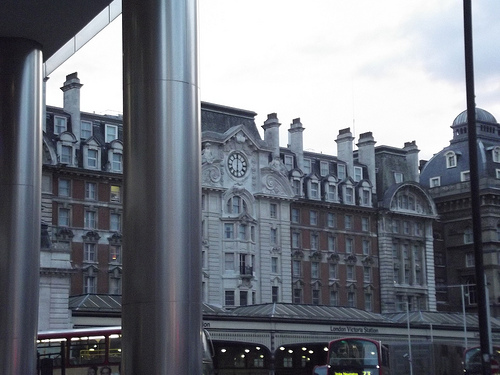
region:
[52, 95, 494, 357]
multi story Victorian style building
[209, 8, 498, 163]
Gray overcast sky above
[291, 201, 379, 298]
Red brick walls on building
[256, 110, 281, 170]
Chimney stack on roof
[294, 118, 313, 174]
Chimney stack on roof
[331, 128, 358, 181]
Chimney stack on roof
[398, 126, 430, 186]
Chimney stack on roof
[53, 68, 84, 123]
Chimney stack on roof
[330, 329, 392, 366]
Scooter mirror with reflection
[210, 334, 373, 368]
Archways below with lights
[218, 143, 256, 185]
Round clock on the building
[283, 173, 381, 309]
Many windows on the building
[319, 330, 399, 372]
The top of a bus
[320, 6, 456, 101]
White clouds in the sky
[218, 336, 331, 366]
Many lights attached from a ceiling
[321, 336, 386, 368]
Front window of a bus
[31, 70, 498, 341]
A large brown and white building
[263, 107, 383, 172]
Chimneys on the building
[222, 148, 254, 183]
Time on the clock is 6:00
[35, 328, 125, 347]
Lights on inside the bus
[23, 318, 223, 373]
A bus on the road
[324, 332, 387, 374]
A bus on the road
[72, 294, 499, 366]
A bus station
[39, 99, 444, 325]
A large brick building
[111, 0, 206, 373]
A metal pole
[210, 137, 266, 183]
A clock on the large building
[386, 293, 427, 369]
A tall street light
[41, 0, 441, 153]
clouds in the sky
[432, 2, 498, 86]
a blue sky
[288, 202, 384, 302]
windows on the building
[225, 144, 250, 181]
clock face on building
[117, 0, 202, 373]
gray pillar on building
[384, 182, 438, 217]
half moon shaped window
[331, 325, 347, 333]
LONDON written on building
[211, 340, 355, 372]
lights in entry way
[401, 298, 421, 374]
tall metal pole in front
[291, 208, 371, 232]
row of windows on building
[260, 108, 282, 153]
pillar on building top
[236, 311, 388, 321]
metal top on roof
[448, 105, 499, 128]
circular dome on building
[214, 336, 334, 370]
lights in a store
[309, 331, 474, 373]
a bus passing in front a building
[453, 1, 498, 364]
a black pole on side of street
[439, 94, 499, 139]
a dome on top a building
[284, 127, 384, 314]
an old building color red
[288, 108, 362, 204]
red building has two chimneys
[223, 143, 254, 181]
a clock on top of a white building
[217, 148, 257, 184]
handles of clock are black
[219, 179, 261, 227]
a window under a clock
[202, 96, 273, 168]
roof of building is black